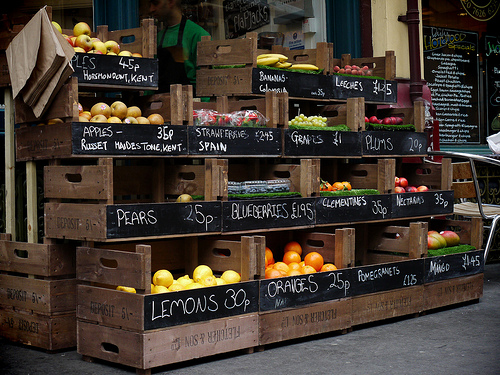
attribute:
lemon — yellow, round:
[155, 267, 173, 292]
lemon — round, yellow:
[203, 266, 228, 286]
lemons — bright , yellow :
[154, 267, 233, 283]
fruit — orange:
[230, 215, 365, 296]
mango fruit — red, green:
[443, 229, 460, 246]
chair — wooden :
[442, 139, 498, 261]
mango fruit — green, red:
[430, 230, 459, 248]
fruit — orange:
[297, 232, 354, 291]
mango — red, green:
[428, 235, 460, 247]